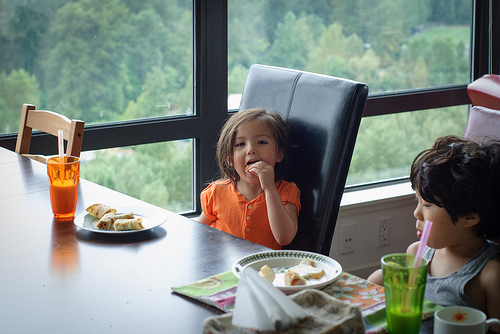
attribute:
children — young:
[188, 94, 479, 266]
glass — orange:
[37, 157, 93, 224]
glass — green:
[374, 245, 437, 327]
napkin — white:
[245, 289, 274, 317]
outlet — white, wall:
[325, 204, 376, 266]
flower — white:
[356, 287, 384, 305]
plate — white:
[77, 213, 162, 246]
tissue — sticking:
[238, 258, 290, 323]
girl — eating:
[195, 103, 300, 222]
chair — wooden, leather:
[291, 50, 374, 156]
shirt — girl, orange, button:
[174, 185, 291, 252]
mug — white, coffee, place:
[190, 271, 229, 311]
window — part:
[89, 38, 182, 102]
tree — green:
[62, 34, 159, 109]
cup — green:
[381, 291, 436, 320]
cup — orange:
[53, 173, 93, 215]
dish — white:
[120, 203, 179, 233]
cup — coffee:
[435, 301, 476, 327]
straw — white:
[50, 116, 78, 150]